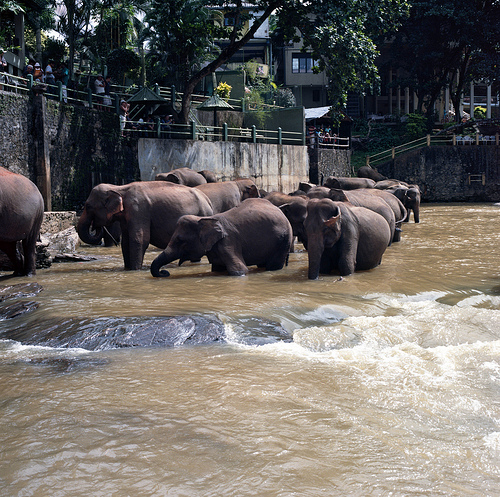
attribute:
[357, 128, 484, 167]
railing — yellow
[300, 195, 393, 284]
elephant — in the water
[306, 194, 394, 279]
elephant — in the water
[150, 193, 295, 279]
elephant — in the water, gray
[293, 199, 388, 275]
elephant — large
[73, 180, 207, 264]
elephant — large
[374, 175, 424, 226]
elephant — drinking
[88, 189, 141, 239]
elephant — standing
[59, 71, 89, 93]
shirt — blue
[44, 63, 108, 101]
people — group, up, above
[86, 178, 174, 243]
elephants — down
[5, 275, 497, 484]
water — stream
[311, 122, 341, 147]
person — watching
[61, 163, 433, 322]
elephants — grouped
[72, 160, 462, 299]
elephants — grouped, grey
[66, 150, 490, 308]
elephants — grouped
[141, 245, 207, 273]
mouth — open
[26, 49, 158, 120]
people — looking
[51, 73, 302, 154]
fence — small, wooden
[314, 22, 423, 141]
tree — green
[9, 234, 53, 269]
legs — hind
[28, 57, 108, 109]
people — looking